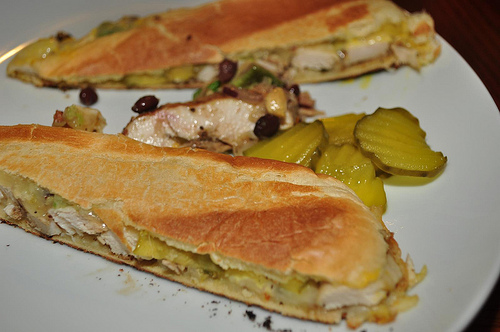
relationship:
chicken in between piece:
[122, 89, 296, 154] [0, 121, 421, 324]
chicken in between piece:
[122, 89, 296, 154] [7, 2, 438, 86]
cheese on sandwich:
[337, 267, 383, 286] [35, 29, 389, 312]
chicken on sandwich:
[45, 202, 139, 260] [35, 29, 389, 312]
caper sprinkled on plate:
[133, 96, 159, 115] [1, 0, 496, 329]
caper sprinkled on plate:
[245, 71, 274, 85] [1, 0, 496, 329]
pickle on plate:
[309, 141, 386, 211] [424, 171, 478, 301]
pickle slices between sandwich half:
[240, 105, 453, 211] [0, 119, 422, 329]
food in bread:
[1, 174, 403, 312] [1, 212, 405, 323]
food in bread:
[1, 174, 403, 312] [5, 124, 386, 284]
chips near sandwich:
[224, 110, 469, 182] [75, 129, 492, 330]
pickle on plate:
[309, 141, 386, 211] [1, 0, 496, 329]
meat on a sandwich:
[119, 85, 261, 149] [6, 116, 433, 328]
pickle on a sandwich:
[309, 141, 386, 211] [6, 116, 433, 328]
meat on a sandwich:
[43, 204, 104, 240] [6, 116, 433, 328]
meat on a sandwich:
[340, 31, 389, 65] [6, 5, 442, 93]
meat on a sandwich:
[309, 270, 389, 315] [6, 5, 442, 93]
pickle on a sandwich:
[309, 141, 386, 211] [6, 5, 442, 93]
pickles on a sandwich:
[127, 66, 168, 91] [6, 5, 442, 93]